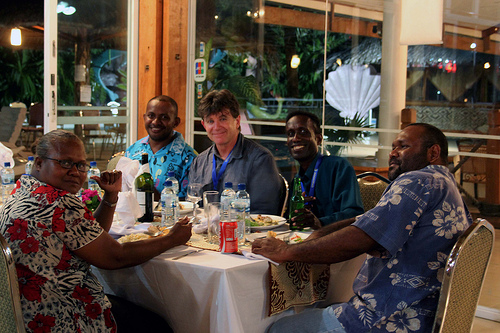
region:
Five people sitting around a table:
[6, 87, 497, 330]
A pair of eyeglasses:
[40, 150, 95, 177]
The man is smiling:
[281, 109, 325, 163]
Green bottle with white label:
[131, 151, 158, 226]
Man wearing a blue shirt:
[123, 90, 199, 202]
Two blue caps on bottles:
[221, 175, 251, 195]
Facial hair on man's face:
[384, 150, 429, 183]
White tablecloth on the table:
[88, 222, 292, 331]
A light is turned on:
[4, 21, 27, 52]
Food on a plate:
[246, 209, 290, 231]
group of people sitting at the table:
[10, 77, 486, 328]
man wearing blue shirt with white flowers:
[306, 112, 476, 332]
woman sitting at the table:
[15, 128, 181, 328]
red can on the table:
[213, 213, 244, 254]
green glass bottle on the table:
[135, 147, 158, 223]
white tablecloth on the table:
[80, 182, 360, 332]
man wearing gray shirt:
[183, 92, 280, 216]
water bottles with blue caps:
[159, 177, 256, 244]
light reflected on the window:
[288, 53, 299, 70]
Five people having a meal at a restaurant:
[0, 87, 472, 331]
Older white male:
[185, 89, 284, 215]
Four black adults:
[8, 93, 474, 322]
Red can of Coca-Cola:
[220, 217, 239, 254]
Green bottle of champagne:
[132, 150, 157, 221]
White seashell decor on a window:
[320, 56, 385, 124]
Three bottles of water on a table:
[155, 180, 249, 239]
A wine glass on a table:
[183, 181, 208, 222]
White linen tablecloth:
[130, 237, 307, 330]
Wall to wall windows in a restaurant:
[5, 2, 492, 154]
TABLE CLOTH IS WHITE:
[185, 275, 213, 302]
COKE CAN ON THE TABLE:
[220, 222, 235, 252]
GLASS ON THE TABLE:
[205, 191, 217, 216]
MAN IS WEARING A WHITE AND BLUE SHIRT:
[407, 230, 443, 270]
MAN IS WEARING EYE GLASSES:
[283, 128, 310, 142]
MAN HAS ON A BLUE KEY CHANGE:
[206, 162, 216, 178]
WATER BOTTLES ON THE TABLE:
[236, 196, 246, 211]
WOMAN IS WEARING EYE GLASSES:
[57, 161, 91, 173]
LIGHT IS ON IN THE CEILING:
[8, 27, 18, 49]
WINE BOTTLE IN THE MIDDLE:
[142, 163, 148, 193]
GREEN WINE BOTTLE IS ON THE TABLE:
[129, 149, 166, 221]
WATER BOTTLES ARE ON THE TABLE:
[162, 177, 269, 244]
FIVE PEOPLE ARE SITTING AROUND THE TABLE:
[33, 93, 473, 323]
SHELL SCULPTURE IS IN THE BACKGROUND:
[324, 60, 381, 134]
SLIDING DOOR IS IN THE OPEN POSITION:
[0, 2, 64, 123]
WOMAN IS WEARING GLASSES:
[28, 129, 98, 206]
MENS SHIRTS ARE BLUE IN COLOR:
[136, 91, 464, 328]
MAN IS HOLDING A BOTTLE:
[282, 135, 324, 214]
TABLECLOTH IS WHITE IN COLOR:
[83, 148, 335, 325]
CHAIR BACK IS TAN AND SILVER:
[426, 220, 493, 331]